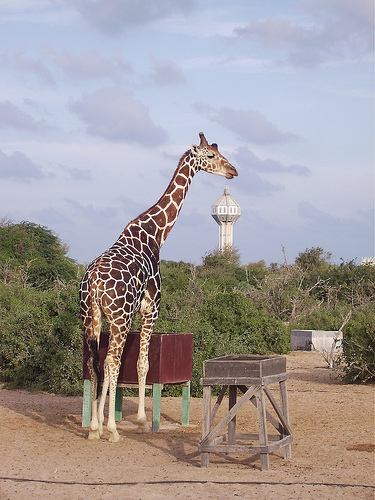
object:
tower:
[211, 186, 242, 257]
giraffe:
[78, 132, 240, 442]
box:
[82, 330, 193, 385]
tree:
[0, 220, 82, 395]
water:
[80, 328, 193, 384]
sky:
[0, 0, 375, 267]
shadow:
[0, 387, 264, 473]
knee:
[136, 360, 149, 375]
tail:
[90, 284, 102, 401]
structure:
[290, 327, 343, 354]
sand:
[1, 350, 375, 499]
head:
[199, 141, 239, 179]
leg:
[136, 278, 161, 423]